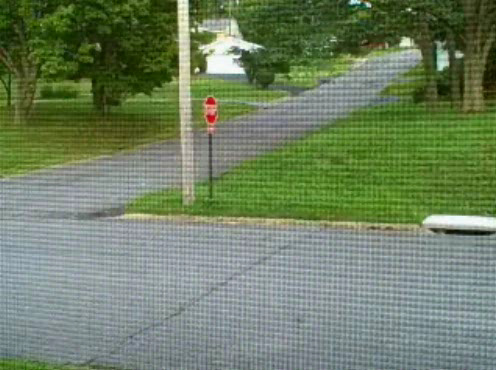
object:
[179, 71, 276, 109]
lot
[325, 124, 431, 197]
grass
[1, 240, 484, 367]
asphalt roads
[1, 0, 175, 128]
two trees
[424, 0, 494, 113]
two trees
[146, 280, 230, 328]
crack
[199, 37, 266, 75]
house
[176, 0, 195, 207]
wooden pole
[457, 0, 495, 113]
trees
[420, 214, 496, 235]
thing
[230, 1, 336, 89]
trees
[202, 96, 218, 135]
sign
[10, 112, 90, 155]
grass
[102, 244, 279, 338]
floor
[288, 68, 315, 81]
grass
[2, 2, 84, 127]
tree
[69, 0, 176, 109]
tree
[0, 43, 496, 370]
field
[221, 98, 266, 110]
small path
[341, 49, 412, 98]
hill